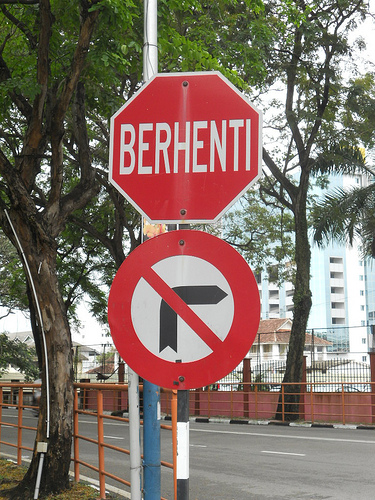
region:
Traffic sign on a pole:
[117, 210, 253, 379]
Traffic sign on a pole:
[116, 67, 252, 221]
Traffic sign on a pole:
[100, 101, 274, 368]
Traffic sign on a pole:
[126, 182, 233, 303]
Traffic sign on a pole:
[141, 26, 237, 380]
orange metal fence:
[2, 381, 179, 494]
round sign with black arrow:
[107, 227, 259, 386]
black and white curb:
[2, 404, 372, 429]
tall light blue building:
[208, 158, 372, 357]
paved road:
[1, 408, 371, 495]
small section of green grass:
[0, 456, 100, 498]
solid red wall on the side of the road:
[85, 384, 369, 422]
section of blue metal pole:
[142, 380, 161, 495]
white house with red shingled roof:
[227, 316, 329, 381]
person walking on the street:
[32, 374, 42, 417]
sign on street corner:
[58, 44, 324, 414]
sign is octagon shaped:
[94, 50, 274, 230]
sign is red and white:
[92, 45, 280, 228]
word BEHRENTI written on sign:
[120, 119, 260, 176]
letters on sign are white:
[115, 118, 258, 178]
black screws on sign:
[178, 77, 187, 219]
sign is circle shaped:
[90, 223, 272, 401]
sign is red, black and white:
[74, 218, 270, 391]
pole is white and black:
[152, 370, 216, 498]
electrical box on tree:
[23, 436, 55, 457]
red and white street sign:
[93, 70, 265, 221]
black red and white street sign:
[100, 229, 259, 394]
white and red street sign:
[102, 66, 261, 233]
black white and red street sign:
[104, 224, 261, 395]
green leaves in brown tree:
[22, 16, 61, 41]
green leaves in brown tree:
[219, 14, 260, 43]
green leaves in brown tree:
[309, 61, 361, 127]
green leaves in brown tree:
[324, 151, 354, 173]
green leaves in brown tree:
[176, 26, 213, 57]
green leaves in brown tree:
[92, 19, 127, 55]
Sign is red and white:
[83, 58, 314, 231]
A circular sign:
[85, 218, 273, 401]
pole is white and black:
[167, 386, 220, 498]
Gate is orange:
[0, 365, 236, 499]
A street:
[116, 404, 373, 490]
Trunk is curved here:
[2, 5, 130, 498]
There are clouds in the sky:
[8, 93, 373, 411]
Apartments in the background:
[119, 1, 374, 423]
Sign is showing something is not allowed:
[98, 226, 285, 406]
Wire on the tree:
[4, 190, 75, 445]